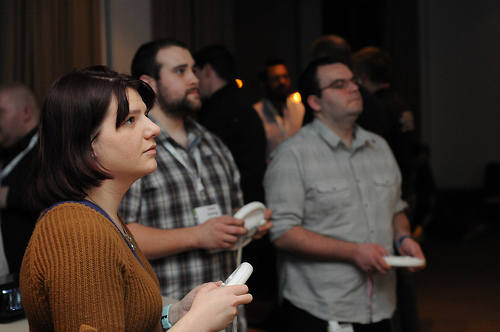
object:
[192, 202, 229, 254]
name badge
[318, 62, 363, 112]
face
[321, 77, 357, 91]
glasses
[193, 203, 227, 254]
key tag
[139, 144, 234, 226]
chest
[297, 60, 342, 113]
hair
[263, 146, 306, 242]
sleeve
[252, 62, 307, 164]
onlooker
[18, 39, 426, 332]
three people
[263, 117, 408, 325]
shirt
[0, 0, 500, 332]
indoors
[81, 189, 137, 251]
necklace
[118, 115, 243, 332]
shirt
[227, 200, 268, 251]
remote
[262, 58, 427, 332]
guy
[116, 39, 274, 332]
guy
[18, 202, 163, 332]
shirt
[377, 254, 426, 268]
controller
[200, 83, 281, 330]
suit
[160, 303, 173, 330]
watch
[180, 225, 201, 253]
wrist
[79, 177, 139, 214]
neck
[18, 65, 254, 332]
people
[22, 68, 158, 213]
dark hair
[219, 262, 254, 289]
controller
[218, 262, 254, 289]
remote controller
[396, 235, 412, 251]
watch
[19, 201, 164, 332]
sweater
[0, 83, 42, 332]
man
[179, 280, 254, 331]
hands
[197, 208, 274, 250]
hands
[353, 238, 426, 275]
hands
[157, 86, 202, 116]
beard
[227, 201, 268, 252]
game control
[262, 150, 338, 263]
arm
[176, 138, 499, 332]
game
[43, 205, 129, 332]
sleeve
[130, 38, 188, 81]
hair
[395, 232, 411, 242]
wrist